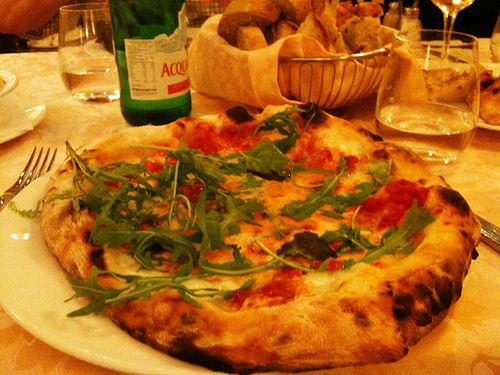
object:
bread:
[218, 0, 278, 43]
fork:
[2, 142, 59, 203]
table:
[1, 38, 499, 373]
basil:
[321, 158, 392, 217]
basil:
[345, 199, 436, 267]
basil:
[197, 198, 282, 281]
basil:
[130, 135, 294, 180]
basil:
[64, 276, 252, 317]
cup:
[372, 27, 484, 167]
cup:
[54, 2, 121, 103]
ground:
[416, 180, 448, 215]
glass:
[370, 29, 483, 177]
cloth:
[184, 13, 340, 109]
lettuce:
[234, 108, 294, 131]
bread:
[234, 23, 267, 51]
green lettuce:
[328, 158, 396, 215]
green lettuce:
[134, 142, 229, 179]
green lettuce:
[171, 269, 254, 304]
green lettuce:
[323, 228, 353, 253]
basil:
[280, 156, 347, 220]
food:
[34, 103, 483, 375]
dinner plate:
[1, 115, 315, 375]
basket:
[192, 14, 409, 111]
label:
[120, 37, 196, 100]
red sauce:
[182, 119, 267, 151]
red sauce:
[363, 179, 429, 215]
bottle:
[105, 0, 190, 127]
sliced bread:
[283, 0, 314, 25]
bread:
[265, 19, 300, 43]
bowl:
[199, 10, 400, 111]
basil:
[173, 212, 198, 234]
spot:
[388, 253, 462, 338]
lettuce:
[93, 190, 138, 213]